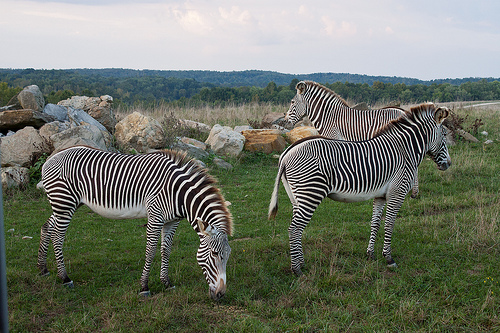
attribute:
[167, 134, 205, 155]
rock — large 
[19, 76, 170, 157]
rock — large 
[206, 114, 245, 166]
rock — large 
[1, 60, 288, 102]
trees — large 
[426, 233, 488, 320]
field — flat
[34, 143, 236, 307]
zebras — black and white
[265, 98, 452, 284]
zebras — black and white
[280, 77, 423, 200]
zebras — black and white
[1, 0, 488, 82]
clouds — thick, layered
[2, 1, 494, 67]
sky — blue and white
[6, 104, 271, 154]
rocks — grey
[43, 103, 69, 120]
rock — large 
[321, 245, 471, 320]
grass — wiry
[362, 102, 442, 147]
mane — black and white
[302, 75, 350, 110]
mane — black and white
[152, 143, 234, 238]
mane — black and white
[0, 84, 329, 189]
rocks — big 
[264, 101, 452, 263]
zebra — standing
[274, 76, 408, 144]
zebra — standing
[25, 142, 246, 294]
zebra — white , black 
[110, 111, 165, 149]
rock — large 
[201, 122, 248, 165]
rock — large 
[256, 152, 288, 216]
tail — black and white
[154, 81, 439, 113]
trees — green, distant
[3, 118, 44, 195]
rock — large 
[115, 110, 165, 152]
rock — large